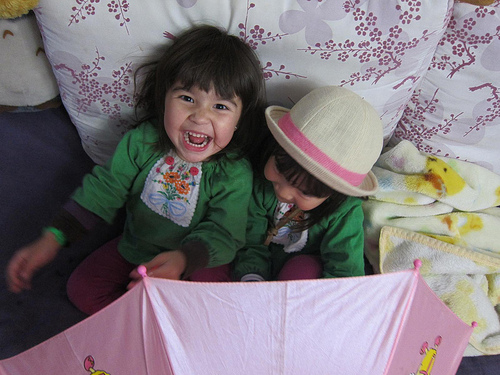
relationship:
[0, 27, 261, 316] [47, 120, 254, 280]
girl wearing green shirt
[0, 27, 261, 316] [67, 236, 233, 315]
girl wearing pants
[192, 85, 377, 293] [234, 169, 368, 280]
girl wearing green shirt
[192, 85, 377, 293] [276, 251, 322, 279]
girl wearing pants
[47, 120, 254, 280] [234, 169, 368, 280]
green shirt matches green shirt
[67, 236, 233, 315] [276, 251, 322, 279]
pants matches pants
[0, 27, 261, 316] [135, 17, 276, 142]
girl has hair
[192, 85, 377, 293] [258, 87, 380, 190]
girl wearing hat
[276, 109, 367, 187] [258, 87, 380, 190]
stripe on hat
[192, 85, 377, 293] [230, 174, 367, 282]
girl wearing shirt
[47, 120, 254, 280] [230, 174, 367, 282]
green shirt matches shirt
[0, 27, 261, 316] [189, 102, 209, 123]
girl has nose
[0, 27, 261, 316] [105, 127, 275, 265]
girl wearing shirt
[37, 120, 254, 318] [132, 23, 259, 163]
toddler has hair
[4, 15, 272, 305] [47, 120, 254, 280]
toddler wearing green shirt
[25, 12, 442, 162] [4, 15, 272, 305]
pillow behind toddler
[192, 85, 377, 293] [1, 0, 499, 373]
girl sitting on bed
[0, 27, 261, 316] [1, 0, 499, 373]
girl sitting on bed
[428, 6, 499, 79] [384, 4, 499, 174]
flowers on pillow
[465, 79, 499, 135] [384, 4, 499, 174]
flowers on pillow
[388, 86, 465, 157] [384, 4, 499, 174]
flowers on pillow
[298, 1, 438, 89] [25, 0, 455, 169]
flowers on pillow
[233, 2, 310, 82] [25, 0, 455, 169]
flowers on pillow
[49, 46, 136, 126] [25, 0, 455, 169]
flowers on pillow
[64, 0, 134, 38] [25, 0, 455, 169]
flowers on pillow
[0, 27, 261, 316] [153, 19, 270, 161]
girl has hair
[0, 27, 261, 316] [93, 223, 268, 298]
girl wearing pants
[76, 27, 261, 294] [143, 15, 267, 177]
girl has head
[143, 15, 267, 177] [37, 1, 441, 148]
head on pillow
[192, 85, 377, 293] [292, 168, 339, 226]
girl has hair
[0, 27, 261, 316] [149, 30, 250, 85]
girl has hair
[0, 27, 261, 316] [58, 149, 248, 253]
girl wearing green shirt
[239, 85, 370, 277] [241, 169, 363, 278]
girl wearing green shirt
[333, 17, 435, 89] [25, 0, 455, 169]
designs on pillow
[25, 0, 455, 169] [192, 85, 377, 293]
pillow behind girl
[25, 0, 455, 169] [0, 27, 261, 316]
pillow behind girl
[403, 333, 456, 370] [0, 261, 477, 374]
design on pink umbrella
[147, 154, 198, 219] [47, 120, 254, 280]
flowers on green shirt